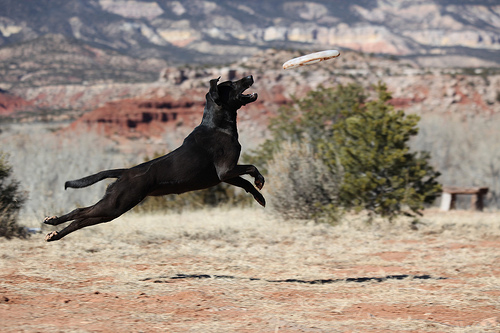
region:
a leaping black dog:
[31, 72, 266, 240]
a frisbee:
[280, 46, 340, 67]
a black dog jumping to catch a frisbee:
[31, 45, 338, 237]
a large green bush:
[245, 77, 441, 212]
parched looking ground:
[3, 220, 498, 332]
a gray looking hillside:
[2, 0, 499, 76]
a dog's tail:
[62, 167, 117, 188]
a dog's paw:
[44, 228, 54, 245]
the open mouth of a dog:
[237, 76, 258, 103]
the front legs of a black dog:
[227, 164, 267, 207]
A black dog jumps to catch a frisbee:
[37, 62, 265, 247]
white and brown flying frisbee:
[280, 41, 345, 78]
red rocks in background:
[57, 83, 181, 134]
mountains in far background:
[27, 6, 488, 44]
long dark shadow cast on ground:
[142, 265, 447, 295]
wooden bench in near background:
[435, 179, 492, 214]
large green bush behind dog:
[245, 75, 448, 222]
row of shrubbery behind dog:
[2, 119, 276, 224]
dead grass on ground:
[17, 270, 492, 323]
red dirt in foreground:
[17, 279, 236, 329]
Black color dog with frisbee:
[27, 31, 379, 252]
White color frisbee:
[282, 36, 344, 78]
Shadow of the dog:
[161, 262, 433, 289]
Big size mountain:
[18, 12, 464, 49]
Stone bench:
[442, 178, 487, 209]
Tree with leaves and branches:
[291, 100, 401, 199]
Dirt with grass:
[146, 222, 374, 323]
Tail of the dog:
[46, 168, 103, 185]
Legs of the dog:
[42, 203, 129, 239]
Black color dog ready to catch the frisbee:
[28, 35, 368, 242]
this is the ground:
[170, 215, 213, 225]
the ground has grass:
[165, 210, 223, 230]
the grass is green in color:
[169, 210, 221, 232]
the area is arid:
[69, 295, 162, 314]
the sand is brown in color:
[58, 294, 115, 311]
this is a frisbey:
[279, 38, 345, 72]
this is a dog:
[41, 50, 275, 245]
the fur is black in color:
[143, 160, 190, 185]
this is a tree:
[328, 85, 443, 225]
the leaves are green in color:
[348, 118, 376, 162]